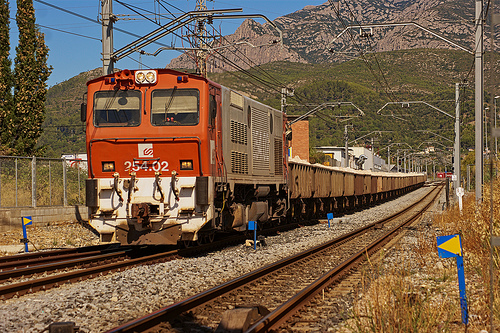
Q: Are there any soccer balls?
A: No, there are no soccer balls.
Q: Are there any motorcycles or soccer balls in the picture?
A: No, there are no soccer balls or motorcycles.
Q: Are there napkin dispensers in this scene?
A: No, there are no napkin dispensers.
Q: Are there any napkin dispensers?
A: No, there are no napkin dispensers.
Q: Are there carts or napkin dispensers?
A: No, there are no napkin dispensers or carts.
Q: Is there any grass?
A: Yes, there is grass.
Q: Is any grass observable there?
A: Yes, there is grass.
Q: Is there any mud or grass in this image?
A: Yes, there is grass.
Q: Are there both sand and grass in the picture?
A: No, there is grass but no sand.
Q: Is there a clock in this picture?
A: No, there are no clocks.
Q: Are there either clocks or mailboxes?
A: No, there are no clocks or mailboxes.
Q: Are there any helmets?
A: No, there are no helmets.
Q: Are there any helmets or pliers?
A: No, there are no helmets or pliers.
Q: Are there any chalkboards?
A: No, there are no chalkboards.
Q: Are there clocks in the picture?
A: No, there are no clocks.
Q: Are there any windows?
A: Yes, there are windows.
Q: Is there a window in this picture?
A: Yes, there are windows.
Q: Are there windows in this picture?
A: Yes, there are windows.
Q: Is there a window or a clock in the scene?
A: Yes, there are windows.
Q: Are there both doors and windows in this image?
A: No, there are windows but no doors.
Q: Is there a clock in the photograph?
A: No, there are no clocks.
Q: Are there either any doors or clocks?
A: No, there are no clocks or doors.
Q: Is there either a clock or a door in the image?
A: No, there are no clocks or doors.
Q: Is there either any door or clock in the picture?
A: No, there are no clocks or doors.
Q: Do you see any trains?
A: Yes, there is a train.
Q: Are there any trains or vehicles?
A: Yes, there is a train.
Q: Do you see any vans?
A: No, there are no vans.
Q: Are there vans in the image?
A: No, there are no vans.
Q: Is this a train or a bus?
A: This is a train.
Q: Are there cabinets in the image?
A: No, there are no cabinets.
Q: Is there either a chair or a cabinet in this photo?
A: No, there are no cabinets or chairs.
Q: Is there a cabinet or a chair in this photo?
A: No, there are no cabinets or chairs.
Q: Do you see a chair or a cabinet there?
A: No, there are no cabinets or chairs.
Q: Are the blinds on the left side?
A: Yes, the blinds are on the left of the image.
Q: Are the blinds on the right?
A: No, the blinds are on the left of the image.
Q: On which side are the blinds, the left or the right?
A: The blinds are on the left of the image.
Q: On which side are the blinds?
A: The blinds are on the left of the image.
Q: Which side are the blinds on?
A: The blinds are on the left of the image.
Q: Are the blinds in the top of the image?
A: Yes, the blinds are in the top of the image.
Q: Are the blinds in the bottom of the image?
A: No, the blinds are in the top of the image.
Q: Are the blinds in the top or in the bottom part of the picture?
A: The blinds are in the top of the image.